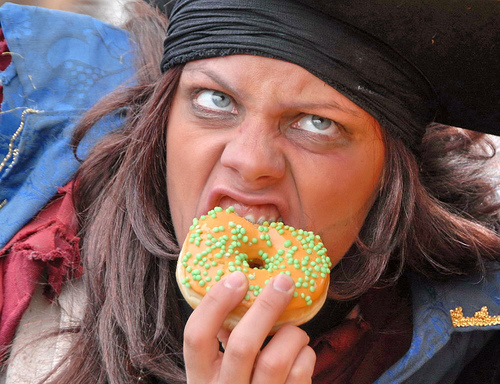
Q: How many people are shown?
A: One.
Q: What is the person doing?
A: Eating.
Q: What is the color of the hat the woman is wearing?
A: Black.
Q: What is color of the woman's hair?
A: Brown.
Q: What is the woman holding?
A: A doughnut.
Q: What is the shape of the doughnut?
A: Round.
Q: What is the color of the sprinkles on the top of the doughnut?
A: Green.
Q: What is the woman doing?
A: Eating a doughnut.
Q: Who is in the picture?
A: A woman.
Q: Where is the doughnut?
A: In the woman's hand.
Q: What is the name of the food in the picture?
A: Doughnut.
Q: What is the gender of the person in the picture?
A: Female.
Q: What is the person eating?
A: A donut.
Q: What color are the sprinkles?
A: Green.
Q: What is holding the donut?
A: A hand.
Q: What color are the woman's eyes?
A: Grey.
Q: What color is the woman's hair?
A: Brown.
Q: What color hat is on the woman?
A: Black.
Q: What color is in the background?
A: Blue.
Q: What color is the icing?
A: Orange.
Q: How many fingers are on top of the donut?
A: Two.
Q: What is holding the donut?
A: A hand.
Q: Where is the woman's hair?
A: On her shoulders.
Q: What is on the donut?
A: Sprinkles and frosting.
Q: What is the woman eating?
A: A donut.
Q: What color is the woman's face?
A: Orange.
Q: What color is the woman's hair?
A: Brown.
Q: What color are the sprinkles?
A: Green.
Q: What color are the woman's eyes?
A: Green.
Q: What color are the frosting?
A: Orange.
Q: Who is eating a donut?
A: A woman.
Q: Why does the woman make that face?
A: To be funny.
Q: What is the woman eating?
A: A donut.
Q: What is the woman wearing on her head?
A: A hat.